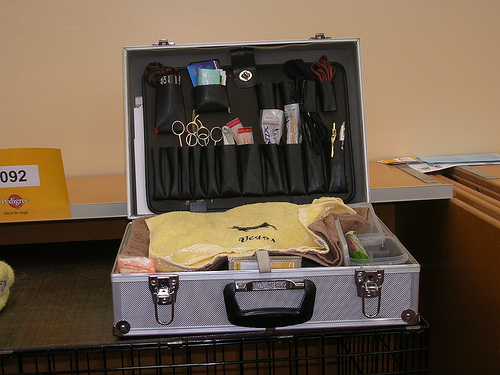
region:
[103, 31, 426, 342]
objects in a brief case.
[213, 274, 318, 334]
the handle is black.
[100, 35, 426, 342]
the briefcase is silver.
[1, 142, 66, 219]
numbers on an envelope.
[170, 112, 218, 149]
scissors in the briefcase.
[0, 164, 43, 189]
092 on the envelope.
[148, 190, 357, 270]
towel on in the briefcase.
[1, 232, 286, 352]
the counter is black.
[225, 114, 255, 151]
bandaids in the briefcase.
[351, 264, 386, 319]
the latch is silver.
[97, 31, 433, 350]
a steel suit case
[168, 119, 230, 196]
bunch of scissors inside case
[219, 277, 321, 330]
handles of a suit case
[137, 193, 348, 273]
hand towels inside case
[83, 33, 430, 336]
an opened suit case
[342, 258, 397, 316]
latches of a suit case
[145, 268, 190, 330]
latches of a suit case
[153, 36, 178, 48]
latches of a suit case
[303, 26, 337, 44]
latches of a suit case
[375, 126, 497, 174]
brochures and pamphlets on table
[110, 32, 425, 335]
Brief case on the desk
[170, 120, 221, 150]
Pairs of scissors in the brief case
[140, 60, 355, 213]
Pouch filled with equipment in the brief case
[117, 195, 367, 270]
Several towels in the brief case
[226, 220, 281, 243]
Logo of the towel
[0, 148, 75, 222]
Post with a number on it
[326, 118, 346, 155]
Several pens in the brief case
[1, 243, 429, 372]
Small table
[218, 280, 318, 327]
Handle of the brief case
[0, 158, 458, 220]
Wooden board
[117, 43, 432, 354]
medical kit in a case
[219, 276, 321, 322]
black handle on the metal case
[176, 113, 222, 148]
top of the scissors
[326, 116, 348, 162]
pens in the case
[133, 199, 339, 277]
towels in the medical case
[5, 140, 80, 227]
yellow sign by the case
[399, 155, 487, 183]
papers laying on the desk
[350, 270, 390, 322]
metal latch on the case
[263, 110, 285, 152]
tube of cream in the case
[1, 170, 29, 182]
numbers on the yellow sign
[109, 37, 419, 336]
the opened silver case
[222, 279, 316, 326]
the black handle on the case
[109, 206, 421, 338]
the bottom of the case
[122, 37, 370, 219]
the top of the case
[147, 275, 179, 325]
the latch on the case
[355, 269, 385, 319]
the latch on the case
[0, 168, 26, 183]
the numbers 092 in black ink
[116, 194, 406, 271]
the contents in the bottom of the case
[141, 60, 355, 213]
the pockets in the top of the case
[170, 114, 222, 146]
the handles of scissors sticking out of a pocket